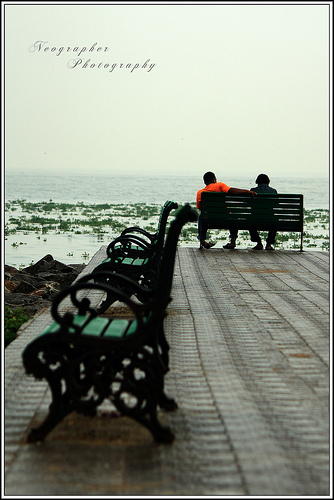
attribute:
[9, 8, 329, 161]
sky — hazy, white, overcast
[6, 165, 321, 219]
ocean — calm, rough, hazy, large, far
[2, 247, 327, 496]
boardwalk — wooden, clean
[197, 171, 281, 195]
people — sitting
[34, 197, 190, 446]
benches — green, black, empty, wooden, metal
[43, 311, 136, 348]
seat — bench, green